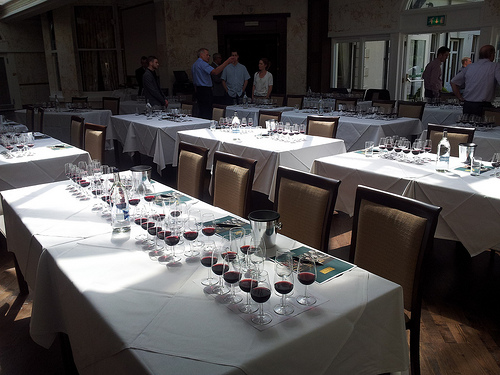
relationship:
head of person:
[436, 42, 454, 64] [420, 41, 463, 105]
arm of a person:
[213, 60, 237, 79] [190, 47, 212, 107]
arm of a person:
[141, 75, 151, 100] [136, 54, 166, 101]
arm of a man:
[265, 73, 279, 93] [221, 50, 249, 105]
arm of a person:
[445, 67, 468, 87] [252, 57, 273, 104]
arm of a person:
[430, 65, 436, 96] [422, 45, 450, 100]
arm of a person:
[143, 81, 164, 100] [139, 54, 171, 116]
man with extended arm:
[190, 48, 237, 121] [211, 50, 237, 82]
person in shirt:
[252, 59, 273, 99] [255, 71, 272, 94]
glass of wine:
[295, 250, 320, 310] [293, 268, 316, 286]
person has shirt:
[252, 59, 273, 99] [250, 67, 277, 97]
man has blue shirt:
[193, 48, 215, 114] [192, 62, 213, 84]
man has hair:
[190, 48, 237, 121] [433, 44, 451, 60]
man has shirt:
[190, 48, 237, 121] [232, 58, 285, 105]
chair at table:
[177, 140, 210, 197] [31, 167, 351, 373]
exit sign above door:
[425, 14, 446, 26] [398, 31, 478, 103]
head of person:
[166, 39, 230, 101] [186, 43, 229, 108]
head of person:
[147, 56, 161, 70] [136, 55, 168, 108]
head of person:
[253, 51, 283, 88] [235, 42, 287, 110]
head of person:
[477, 44, 493, 59] [450, 42, 495, 124]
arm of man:
[205, 63, 228, 76] [190, 48, 237, 121]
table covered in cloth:
[4, 169, 417, 374] [2, 173, 422, 355]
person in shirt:
[252, 59, 273, 99] [252, 70, 279, 92]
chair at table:
[343, 154, 450, 374] [4, 169, 417, 374]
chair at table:
[166, 142, 211, 199] [4, 169, 417, 374]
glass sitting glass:
[268, 261, 293, 317] [248, 269, 271, 328]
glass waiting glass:
[296, 256, 318, 305] [248, 269, 271, 328]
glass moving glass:
[238, 265, 259, 312] [248, 269, 271, 328]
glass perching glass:
[198, 238, 220, 285] [248, 269, 271, 328]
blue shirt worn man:
[192, 58, 215, 87] [221, 50, 251, 106]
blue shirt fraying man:
[189, 56, 213, 88] [221, 50, 251, 106]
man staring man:
[190, 48, 237, 121] [221, 50, 251, 106]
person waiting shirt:
[252, 59, 273, 99] [258, 81, 271, 90]